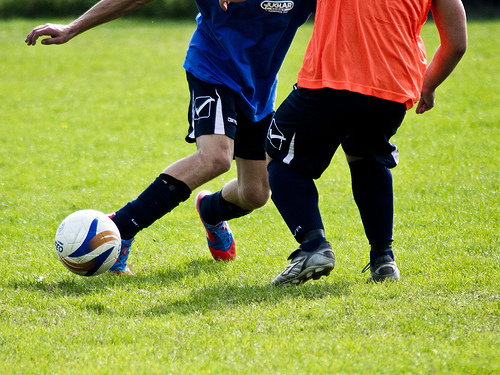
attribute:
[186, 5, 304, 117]
blue shirt — sport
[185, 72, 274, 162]
shorts — pair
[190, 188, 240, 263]
shoe — blue, red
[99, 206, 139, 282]
shoe — blue, red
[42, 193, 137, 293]
ball — white, soccer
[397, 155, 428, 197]
ground — black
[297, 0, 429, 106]
orange shirt — sports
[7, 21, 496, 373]
grass — green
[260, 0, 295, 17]
logo — white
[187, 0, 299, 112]
shirt — blue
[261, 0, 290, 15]
letters — white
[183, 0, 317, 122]
shirt — blue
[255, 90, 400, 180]
shorts — black, sport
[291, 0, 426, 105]
shirt — orange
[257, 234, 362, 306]
cleat — black, grey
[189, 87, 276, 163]
shorts — black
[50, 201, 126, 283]
ball — white, blue, gold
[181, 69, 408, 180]
shorts — black, white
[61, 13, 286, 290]
player — soccer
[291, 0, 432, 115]
shirt — orange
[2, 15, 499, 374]
field — grassy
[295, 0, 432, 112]
tee shirt — large, orange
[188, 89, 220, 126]
print — white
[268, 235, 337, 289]
shoes — gray